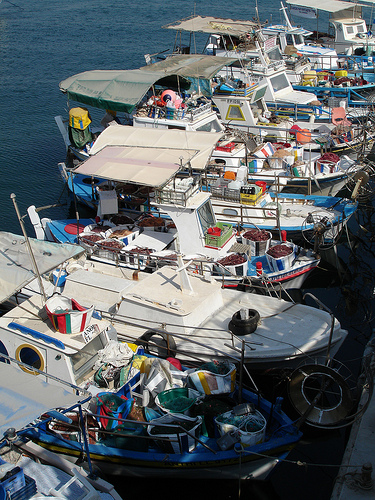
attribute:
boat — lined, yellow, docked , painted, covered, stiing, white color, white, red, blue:
[55, 107, 357, 250]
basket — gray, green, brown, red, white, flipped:
[157, 384, 209, 423]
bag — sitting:
[214, 405, 267, 443]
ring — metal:
[284, 357, 372, 428]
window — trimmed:
[15, 344, 43, 374]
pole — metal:
[84, 412, 182, 429]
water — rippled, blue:
[2, 1, 374, 495]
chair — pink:
[333, 106, 354, 134]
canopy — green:
[60, 65, 189, 113]